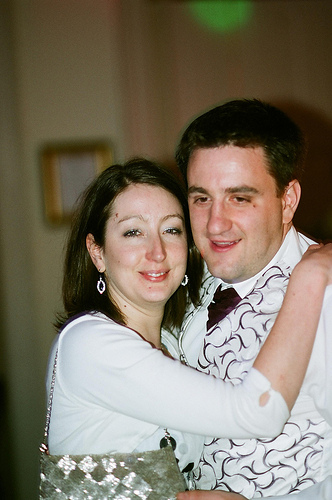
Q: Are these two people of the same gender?
A: No, they are both male and female.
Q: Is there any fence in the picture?
A: No, there are no fences.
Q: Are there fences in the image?
A: No, there are no fences.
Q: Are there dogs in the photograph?
A: No, there are no dogs.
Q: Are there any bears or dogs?
A: No, there are no dogs or bears.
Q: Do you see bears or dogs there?
A: No, there are no dogs or bears.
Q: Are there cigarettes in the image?
A: No, there are no cigarettes.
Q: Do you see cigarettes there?
A: No, there are no cigarettes.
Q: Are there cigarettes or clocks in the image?
A: No, there are no cigarettes or clocks.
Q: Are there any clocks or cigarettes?
A: No, there are no cigarettes or clocks.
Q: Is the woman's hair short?
A: No, the hair is long.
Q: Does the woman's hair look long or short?
A: The hair is long.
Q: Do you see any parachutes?
A: No, there are no parachutes.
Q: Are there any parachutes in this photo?
A: No, there are no parachutes.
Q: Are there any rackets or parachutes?
A: No, there are no parachutes or rackets.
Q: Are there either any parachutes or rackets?
A: No, there are no parachutes or rackets.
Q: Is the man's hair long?
A: No, the hair is short.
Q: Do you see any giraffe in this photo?
A: No, there are no giraffes.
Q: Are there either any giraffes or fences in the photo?
A: No, there are no giraffes or fences.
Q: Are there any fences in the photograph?
A: No, there are no fences.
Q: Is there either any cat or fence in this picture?
A: No, there are no fences or cats.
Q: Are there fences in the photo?
A: No, there are no fences.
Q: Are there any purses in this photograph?
A: Yes, there is a purse.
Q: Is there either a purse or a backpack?
A: Yes, there is a purse.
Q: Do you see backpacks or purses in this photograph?
A: Yes, there is a purse.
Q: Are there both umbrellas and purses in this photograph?
A: No, there is a purse but no umbrellas.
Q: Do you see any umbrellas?
A: No, there are no umbrellas.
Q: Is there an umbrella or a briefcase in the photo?
A: No, there are no umbrellas or briefcases.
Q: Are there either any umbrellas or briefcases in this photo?
A: No, there are no umbrellas or briefcases.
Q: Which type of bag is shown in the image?
A: The bag is a purse.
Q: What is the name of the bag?
A: The bag is a purse.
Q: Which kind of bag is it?
A: The bag is a purse.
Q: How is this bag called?
A: That is a purse.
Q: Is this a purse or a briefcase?
A: This is a purse.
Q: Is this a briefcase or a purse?
A: This is a purse.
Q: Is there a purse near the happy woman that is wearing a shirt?
A: Yes, there is a purse near the woman.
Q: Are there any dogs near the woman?
A: No, there is a purse near the woman.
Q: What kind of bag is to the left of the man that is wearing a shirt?
A: The bag is a purse.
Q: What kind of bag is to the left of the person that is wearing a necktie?
A: The bag is a purse.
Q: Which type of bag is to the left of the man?
A: The bag is a purse.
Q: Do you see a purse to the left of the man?
A: Yes, there is a purse to the left of the man.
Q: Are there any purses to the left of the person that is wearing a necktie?
A: Yes, there is a purse to the left of the man.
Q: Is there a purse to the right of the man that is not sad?
A: No, the purse is to the left of the man.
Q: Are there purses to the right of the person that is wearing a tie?
A: No, the purse is to the left of the man.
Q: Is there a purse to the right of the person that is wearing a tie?
A: No, the purse is to the left of the man.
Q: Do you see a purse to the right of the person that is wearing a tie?
A: No, the purse is to the left of the man.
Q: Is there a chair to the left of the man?
A: No, there is a purse to the left of the man.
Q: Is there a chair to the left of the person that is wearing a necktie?
A: No, there is a purse to the left of the man.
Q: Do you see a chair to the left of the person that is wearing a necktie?
A: No, there is a purse to the left of the man.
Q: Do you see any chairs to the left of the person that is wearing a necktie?
A: No, there is a purse to the left of the man.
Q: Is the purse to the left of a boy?
A: No, the purse is to the left of the man.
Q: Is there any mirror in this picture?
A: Yes, there is a mirror.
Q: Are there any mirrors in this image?
A: Yes, there is a mirror.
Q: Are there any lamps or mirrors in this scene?
A: Yes, there is a mirror.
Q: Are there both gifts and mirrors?
A: No, there is a mirror but no gifts.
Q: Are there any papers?
A: No, there are no papers.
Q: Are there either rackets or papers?
A: No, there are no papers or rackets.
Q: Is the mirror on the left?
A: Yes, the mirror is on the left of the image.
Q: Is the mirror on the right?
A: No, the mirror is on the left of the image.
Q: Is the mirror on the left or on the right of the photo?
A: The mirror is on the left of the image.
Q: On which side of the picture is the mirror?
A: The mirror is on the left of the image.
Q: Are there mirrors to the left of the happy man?
A: Yes, there is a mirror to the left of the man.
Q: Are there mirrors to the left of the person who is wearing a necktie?
A: Yes, there is a mirror to the left of the man.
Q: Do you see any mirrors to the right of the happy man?
A: No, the mirror is to the left of the man.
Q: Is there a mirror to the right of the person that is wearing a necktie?
A: No, the mirror is to the left of the man.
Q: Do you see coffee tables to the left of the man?
A: No, there is a mirror to the left of the man.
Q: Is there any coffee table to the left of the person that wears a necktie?
A: No, there is a mirror to the left of the man.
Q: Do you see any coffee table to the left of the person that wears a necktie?
A: No, there is a mirror to the left of the man.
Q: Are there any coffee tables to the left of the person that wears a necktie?
A: No, there is a mirror to the left of the man.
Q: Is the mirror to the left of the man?
A: Yes, the mirror is to the left of the man.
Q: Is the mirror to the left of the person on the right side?
A: Yes, the mirror is to the left of the man.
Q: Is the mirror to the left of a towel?
A: No, the mirror is to the left of the man.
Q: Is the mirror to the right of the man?
A: No, the mirror is to the left of the man.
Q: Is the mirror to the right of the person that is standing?
A: No, the mirror is to the left of the man.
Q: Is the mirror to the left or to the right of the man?
A: The mirror is to the left of the man.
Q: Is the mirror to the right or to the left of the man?
A: The mirror is to the left of the man.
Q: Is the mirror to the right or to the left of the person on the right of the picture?
A: The mirror is to the left of the man.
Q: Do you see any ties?
A: Yes, there is a tie.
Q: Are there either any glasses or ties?
A: Yes, there is a tie.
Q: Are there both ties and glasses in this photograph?
A: No, there is a tie but no glasses.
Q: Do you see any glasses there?
A: No, there are no glasses.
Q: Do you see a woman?
A: Yes, there is a woman.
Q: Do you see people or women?
A: Yes, there is a woman.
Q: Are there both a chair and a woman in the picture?
A: No, there is a woman but no chairs.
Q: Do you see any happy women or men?
A: Yes, there is a happy woman.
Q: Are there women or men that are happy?
A: Yes, the woman is happy.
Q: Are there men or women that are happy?
A: Yes, the woman is happy.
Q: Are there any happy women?
A: Yes, there is a happy woman.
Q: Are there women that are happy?
A: Yes, there is a woman that is happy.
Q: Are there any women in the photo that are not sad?
A: Yes, there is a happy woman.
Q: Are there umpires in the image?
A: No, there are no umpires.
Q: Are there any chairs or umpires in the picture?
A: No, there are no umpires or chairs.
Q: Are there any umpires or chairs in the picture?
A: No, there are no umpires or chairs.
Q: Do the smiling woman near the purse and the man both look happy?
A: Yes, both the woman and the man are happy.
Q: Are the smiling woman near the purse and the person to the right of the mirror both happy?
A: Yes, both the woman and the man are happy.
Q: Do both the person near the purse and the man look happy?
A: Yes, both the woman and the man are happy.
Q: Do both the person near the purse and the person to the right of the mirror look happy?
A: Yes, both the woman and the man are happy.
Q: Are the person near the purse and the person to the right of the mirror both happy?
A: Yes, both the woman and the man are happy.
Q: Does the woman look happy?
A: Yes, the woman is happy.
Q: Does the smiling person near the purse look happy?
A: Yes, the woman is happy.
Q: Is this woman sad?
A: No, the woman is happy.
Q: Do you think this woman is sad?
A: No, the woman is happy.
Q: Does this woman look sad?
A: No, the woman is happy.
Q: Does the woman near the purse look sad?
A: No, the woman is happy.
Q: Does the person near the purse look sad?
A: No, the woman is happy.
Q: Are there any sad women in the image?
A: No, there is a woman but she is happy.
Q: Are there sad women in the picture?
A: No, there is a woman but she is happy.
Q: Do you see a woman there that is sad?
A: No, there is a woman but she is happy.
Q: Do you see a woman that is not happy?
A: No, there is a woman but she is happy.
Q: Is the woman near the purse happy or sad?
A: The woman is happy.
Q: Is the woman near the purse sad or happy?
A: The woman is happy.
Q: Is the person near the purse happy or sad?
A: The woman is happy.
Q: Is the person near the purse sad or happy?
A: The woman is happy.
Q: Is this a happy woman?
A: Yes, this is a happy woman.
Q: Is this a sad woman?
A: No, this is a happy woman.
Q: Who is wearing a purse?
A: The woman is wearing a purse.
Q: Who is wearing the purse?
A: The woman is wearing a purse.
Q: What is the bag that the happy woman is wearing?
A: The bag is a purse.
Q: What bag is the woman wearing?
A: The woman is wearing a purse.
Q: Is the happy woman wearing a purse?
A: Yes, the woman is wearing a purse.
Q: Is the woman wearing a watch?
A: No, the woman is wearing a purse.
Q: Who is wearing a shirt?
A: The woman is wearing a shirt.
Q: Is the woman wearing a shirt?
A: Yes, the woman is wearing a shirt.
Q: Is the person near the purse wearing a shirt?
A: Yes, the woman is wearing a shirt.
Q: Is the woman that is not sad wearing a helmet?
A: No, the woman is wearing a shirt.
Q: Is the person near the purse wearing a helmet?
A: No, the woman is wearing a shirt.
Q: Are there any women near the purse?
A: Yes, there is a woman near the purse.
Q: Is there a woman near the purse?
A: Yes, there is a woman near the purse.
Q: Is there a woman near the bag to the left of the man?
A: Yes, there is a woman near the purse.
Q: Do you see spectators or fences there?
A: No, there are no fences or spectators.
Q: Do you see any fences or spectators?
A: No, there are no fences or spectators.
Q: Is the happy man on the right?
A: Yes, the man is on the right of the image.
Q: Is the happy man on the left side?
A: No, the man is on the right of the image.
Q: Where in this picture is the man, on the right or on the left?
A: The man is on the right of the image.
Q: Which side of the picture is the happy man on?
A: The man is on the right of the image.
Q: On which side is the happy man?
A: The man is on the right of the image.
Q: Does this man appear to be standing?
A: Yes, the man is standing.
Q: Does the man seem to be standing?
A: Yes, the man is standing.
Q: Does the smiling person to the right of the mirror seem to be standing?
A: Yes, the man is standing.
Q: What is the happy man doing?
A: The man is standing.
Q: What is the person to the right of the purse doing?
A: The man is standing.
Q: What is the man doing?
A: The man is standing.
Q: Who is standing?
A: The man is standing.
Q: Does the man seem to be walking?
A: No, the man is standing.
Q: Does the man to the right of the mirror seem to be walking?
A: No, the man is standing.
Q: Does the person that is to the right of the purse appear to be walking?
A: No, the man is standing.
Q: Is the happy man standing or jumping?
A: The man is standing.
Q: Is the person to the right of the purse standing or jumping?
A: The man is standing.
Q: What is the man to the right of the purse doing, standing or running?
A: The man is standing.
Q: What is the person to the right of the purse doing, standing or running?
A: The man is standing.